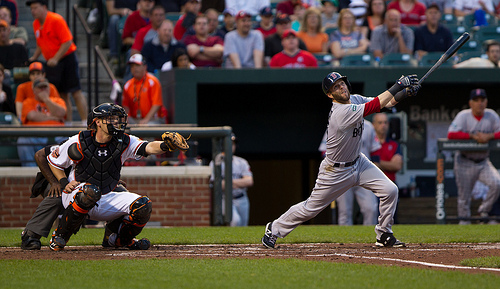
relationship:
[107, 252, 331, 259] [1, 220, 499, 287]
lines on baseball field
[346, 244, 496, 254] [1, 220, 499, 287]
lines on baseball field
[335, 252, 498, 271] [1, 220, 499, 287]
lines on baseball field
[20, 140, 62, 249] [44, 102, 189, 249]
umpire behind catcher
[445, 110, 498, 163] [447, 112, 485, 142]
shirt worn over shirt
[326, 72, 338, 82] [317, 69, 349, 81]
emblem on helmet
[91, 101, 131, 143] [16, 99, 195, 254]
face plate on catcher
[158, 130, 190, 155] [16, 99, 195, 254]
glove on catcher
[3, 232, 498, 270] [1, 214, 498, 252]
dirt in middle of grass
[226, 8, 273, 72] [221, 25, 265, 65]
man wears shirt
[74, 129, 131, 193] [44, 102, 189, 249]
protector on catcher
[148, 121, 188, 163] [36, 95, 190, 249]
glove on hand of catcher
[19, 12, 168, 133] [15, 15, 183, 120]
spectators wearing orange shirts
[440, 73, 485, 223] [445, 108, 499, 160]
man wearing a shirt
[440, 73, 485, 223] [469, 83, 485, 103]
man wearing a cap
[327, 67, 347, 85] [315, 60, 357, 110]
helmet on head